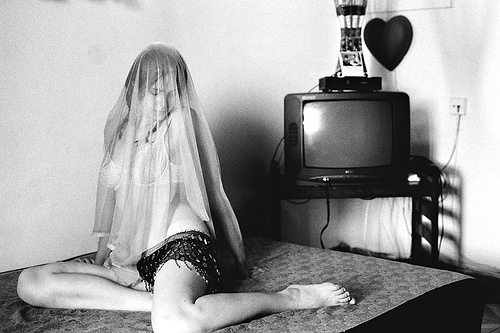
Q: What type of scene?
A: Indoor.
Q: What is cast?
A: Reflection.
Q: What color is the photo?
A: Black and white.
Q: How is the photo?
A: Clear.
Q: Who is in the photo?
A: A person.